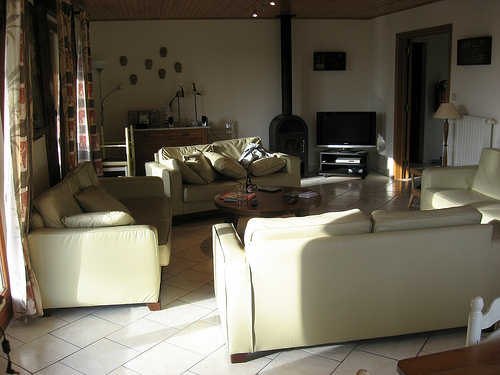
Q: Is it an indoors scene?
A: Yes, it is indoors.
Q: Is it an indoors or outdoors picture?
A: It is indoors.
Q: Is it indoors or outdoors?
A: It is indoors.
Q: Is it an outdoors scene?
A: No, it is indoors.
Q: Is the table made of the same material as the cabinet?
A: Yes, both the table and the cabinet are made of wood.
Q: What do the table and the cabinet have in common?
A: The material, both the table and the cabinet are wooden.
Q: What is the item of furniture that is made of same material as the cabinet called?
A: The piece of furniture is a table.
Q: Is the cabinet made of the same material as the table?
A: Yes, both the cabinet and the table are made of wood.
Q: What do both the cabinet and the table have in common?
A: The material, both the cabinet and the table are wooden.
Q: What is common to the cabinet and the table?
A: The material, both the cabinet and the table are wooden.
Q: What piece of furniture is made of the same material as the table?
A: The cabinet is made of the same material as the table.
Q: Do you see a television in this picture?
A: Yes, there is a television.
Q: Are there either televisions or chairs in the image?
A: Yes, there is a television.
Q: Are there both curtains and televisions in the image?
A: Yes, there are both a television and a curtain.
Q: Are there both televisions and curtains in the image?
A: Yes, there are both a television and a curtain.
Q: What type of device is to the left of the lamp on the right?
A: The device is a television.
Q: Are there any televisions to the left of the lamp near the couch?
A: Yes, there is a television to the left of the lamp.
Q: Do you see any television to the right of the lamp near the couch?
A: No, the television is to the left of the lamp.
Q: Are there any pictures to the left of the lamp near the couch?
A: No, there is a television to the left of the lamp.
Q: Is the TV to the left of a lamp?
A: Yes, the TV is to the left of a lamp.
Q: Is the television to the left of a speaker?
A: No, the television is to the left of a lamp.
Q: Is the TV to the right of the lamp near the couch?
A: No, the TV is to the left of the lamp.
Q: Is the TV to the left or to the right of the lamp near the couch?
A: The TV is to the left of the lamp.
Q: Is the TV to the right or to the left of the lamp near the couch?
A: The TV is to the left of the lamp.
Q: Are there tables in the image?
A: Yes, there is a table.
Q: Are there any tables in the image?
A: Yes, there is a table.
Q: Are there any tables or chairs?
A: Yes, there is a table.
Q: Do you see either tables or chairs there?
A: Yes, there is a table.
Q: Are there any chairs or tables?
A: Yes, there is a table.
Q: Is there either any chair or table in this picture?
A: Yes, there is a table.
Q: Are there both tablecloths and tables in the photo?
A: No, there is a table but no tablecloths.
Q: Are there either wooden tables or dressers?
A: Yes, there is a wood table.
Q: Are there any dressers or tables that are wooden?
A: Yes, the table is wooden.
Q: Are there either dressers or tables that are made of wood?
A: Yes, the table is made of wood.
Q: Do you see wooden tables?
A: Yes, there is a wood table.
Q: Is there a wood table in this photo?
A: Yes, there is a wood table.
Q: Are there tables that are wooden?
A: Yes, there is a table that is wooden.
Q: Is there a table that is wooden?
A: Yes, there is a table that is wooden.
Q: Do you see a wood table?
A: Yes, there is a table that is made of wood.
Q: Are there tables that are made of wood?
A: Yes, there is a table that is made of wood.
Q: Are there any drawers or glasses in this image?
A: No, there are no glasses or drawers.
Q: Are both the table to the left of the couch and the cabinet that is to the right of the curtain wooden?
A: Yes, both the table and the cabinet are wooden.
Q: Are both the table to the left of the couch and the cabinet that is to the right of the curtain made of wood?
A: Yes, both the table and the cabinet are made of wood.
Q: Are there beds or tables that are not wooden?
A: No, there is a table but it is wooden.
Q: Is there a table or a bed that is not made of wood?
A: No, there is a table but it is made of wood.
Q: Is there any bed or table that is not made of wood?
A: No, there is a table but it is made of wood.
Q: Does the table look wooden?
A: Yes, the table is wooden.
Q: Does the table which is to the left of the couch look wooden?
A: Yes, the table is wooden.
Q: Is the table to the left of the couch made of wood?
A: Yes, the table is made of wood.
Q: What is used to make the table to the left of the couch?
A: The table is made of wood.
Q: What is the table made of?
A: The table is made of wood.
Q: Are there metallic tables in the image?
A: No, there is a table but it is wooden.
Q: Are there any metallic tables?
A: No, there is a table but it is wooden.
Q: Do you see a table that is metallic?
A: No, there is a table but it is wooden.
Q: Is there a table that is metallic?
A: No, there is a table but it is wooden.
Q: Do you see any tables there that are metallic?
A: No, there is a table but it is wooden.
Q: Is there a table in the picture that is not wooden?
A: No, there is a table but it is wooden.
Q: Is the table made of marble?
A: No, the table is made of wood.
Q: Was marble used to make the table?
A: No, the table is made of wood.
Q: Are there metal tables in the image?
A: No, there is a table but it is made of wood.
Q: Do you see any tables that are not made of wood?
A: No, there is a table but it is made of wood.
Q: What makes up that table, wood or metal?
A: The table is made of wood.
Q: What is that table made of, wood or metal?
A: The table is made of wood.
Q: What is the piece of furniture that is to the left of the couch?
A: The piece of furniture is a table.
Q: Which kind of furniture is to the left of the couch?
A: The piece of furniture is a table.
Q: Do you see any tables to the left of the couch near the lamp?
A: Yes, there is a table to the left of the couch.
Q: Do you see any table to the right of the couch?
A: No, the table is to the left of the couch.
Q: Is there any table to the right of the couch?
A: No, the table is to the left of the couch.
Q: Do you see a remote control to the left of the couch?
A: No, there is a table to the left of the couch.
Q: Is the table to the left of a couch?
A: Yes, the table is to the left of a couch.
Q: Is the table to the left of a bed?
A: No, the table is to the left of a couch.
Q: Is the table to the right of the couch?
A: No, the table is to the left of the couch.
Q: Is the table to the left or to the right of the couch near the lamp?
A: The table is to the left of the couch.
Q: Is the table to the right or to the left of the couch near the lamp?
A: The table is to the left of the couch.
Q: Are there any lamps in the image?
A: Yes, there is a lamp.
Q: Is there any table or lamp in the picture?
A: Yes, there is a lamp.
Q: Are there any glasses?
A: No, there are no glasses.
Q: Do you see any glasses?
A: No, there are no glasses.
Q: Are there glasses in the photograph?
A: No, there are no glasses.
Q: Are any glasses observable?
A: No, there are no glasses.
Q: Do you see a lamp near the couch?
A: Yes, there is a lamp near the couch.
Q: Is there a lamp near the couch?
A: Yes, there is a lamp near the couch.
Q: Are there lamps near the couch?
A: Yes, there is a lamp near the couch.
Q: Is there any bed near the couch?
A: No, there is a lamp near the couch.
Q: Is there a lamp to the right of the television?
A: Yes, there is a lamp to the right of the television.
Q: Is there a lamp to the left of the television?
A: No, the lamp is to the right of the television.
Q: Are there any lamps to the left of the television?
A: No, the lamp is to the right of the television.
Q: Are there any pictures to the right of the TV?
A: No, there is a lamp to the right of the TV.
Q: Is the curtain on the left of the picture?
A: Yes, the curtain is on the left of the image.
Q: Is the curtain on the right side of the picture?
A: No, the curtain is on the left of the image.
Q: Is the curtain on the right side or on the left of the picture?
A: The curtain is on the left of the image.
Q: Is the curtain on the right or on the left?
A: The curtain is on the left of the image.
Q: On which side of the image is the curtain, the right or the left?
A: The curtain is on the left of the image.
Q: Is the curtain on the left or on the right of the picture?
A: The curtain is on the left of the image.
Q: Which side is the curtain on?
A: The curtain is on the left of the image.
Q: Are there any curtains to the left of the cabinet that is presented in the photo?
A: Yes, there is a curtain to the left of the cabinet.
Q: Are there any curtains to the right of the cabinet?
A: No, the curtain is to the left of the cabinet.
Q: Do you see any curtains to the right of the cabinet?
A: No, the curtain is to the left of the cabinet.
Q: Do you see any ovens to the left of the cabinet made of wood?
A: No, there is a curtain to the left of the cabinet.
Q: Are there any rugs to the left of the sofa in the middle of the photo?
A: No, there is a curtain to the left of the sofa.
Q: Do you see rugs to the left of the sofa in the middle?
A: No, there is a curtain to the left of the sofa.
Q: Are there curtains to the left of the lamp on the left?
A: Yes, there is a curtain to the left of the lamp.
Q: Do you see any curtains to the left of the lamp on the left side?
A: Yes, there is a curtain to the left of the lamp.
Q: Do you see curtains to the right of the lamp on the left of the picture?
A: No, the curtain is to the left of the lamp.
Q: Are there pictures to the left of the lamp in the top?
A: No, there is a curtain to the left of the lamp.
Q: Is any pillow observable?
A: Yes, there are pillows.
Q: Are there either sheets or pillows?
A: Yes, there are pillows.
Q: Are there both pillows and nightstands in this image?
A: No, there are pillows but no nightstands.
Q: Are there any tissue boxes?
A: No, there are no tissue boxes.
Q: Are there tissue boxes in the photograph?
A: No, there are no tissue boxes.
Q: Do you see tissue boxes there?
A: No, there are no tissue boxes.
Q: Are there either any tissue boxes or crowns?
A: No, there are no tissue boxes or crowns.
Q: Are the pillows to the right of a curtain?
A: Yes, the pillows are to the right of a curtain.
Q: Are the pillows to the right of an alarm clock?
A: No, the pillows are to the right of a curtain.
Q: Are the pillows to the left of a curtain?
A: No, the pillows are to the right of a curtain.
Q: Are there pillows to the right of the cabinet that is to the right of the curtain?
A: Yes, there are pillows to the right of the cabinet.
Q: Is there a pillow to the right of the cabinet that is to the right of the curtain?
A: Yes, there are pillows to the right of the cabinet.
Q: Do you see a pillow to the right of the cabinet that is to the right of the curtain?
A: Yes, there are pillows to the right of the cabinet.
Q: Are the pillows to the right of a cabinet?
A: Yes, the pillows are to the right of a cabinet.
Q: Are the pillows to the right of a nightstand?
A: No, the pillows are to the right of a cabinet.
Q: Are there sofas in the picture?
A: Yes, there is a sofa.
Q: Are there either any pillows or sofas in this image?
A: Yes, there is a sofa.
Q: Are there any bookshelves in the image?
A: No, there are no bookshelves.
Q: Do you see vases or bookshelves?
A: No, there are no bookshelves or vases.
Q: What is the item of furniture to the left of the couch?
A: The piece of furniture is a sofa.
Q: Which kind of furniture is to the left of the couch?
A: The piece of furniture is a sofa.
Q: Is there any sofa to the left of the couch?
A: Yes, there is a sofa to the left of the couch.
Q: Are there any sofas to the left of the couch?
A: Yes, there is a sofa to the left of the couch.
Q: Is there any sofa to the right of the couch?
A: No, the sofa is to the left of the couch.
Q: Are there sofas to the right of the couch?
A: No, the sofa is to the left of the couch.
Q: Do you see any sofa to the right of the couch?
A: No, the sofa is to the left of the couch.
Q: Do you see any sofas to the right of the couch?
A: No, the sofa is to the left of the couch.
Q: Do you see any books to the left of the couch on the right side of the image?
A: No, there is a sofa to the left of the couch.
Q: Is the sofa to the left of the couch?
A: Yes, the sofa is to the left of the couch.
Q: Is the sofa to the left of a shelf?
A: No, the sofa is to the left of the couch.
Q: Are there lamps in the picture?
A: Yes, there is a lamp.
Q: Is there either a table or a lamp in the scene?
A: Yes, there is a lamp.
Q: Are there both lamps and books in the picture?
A: No, there is a lamp but no books.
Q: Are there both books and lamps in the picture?
A: No, there is a lamp but no books.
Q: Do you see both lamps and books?
A: No, there is a lamp but no books.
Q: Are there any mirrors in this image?
A: No, there are no mirrors.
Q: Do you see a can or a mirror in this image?
A: No, there are no mirrors or cans.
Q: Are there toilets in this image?
A: No, there are no toilets.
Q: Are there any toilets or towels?
A: No, there are no toilets or towels.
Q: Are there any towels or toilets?
A: No, there are no toilets or towels.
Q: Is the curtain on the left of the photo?
A: Yes, the curtain is on the left of the image.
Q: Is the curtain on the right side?
A: No, the curtain is on the left of the image.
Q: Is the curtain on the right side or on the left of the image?
A: The curtain is on the left of the image.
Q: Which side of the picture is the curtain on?
A: The curtain is on the left of the image.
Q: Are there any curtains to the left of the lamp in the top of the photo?
A: Yes, there is a curtain to the left of the lamp.